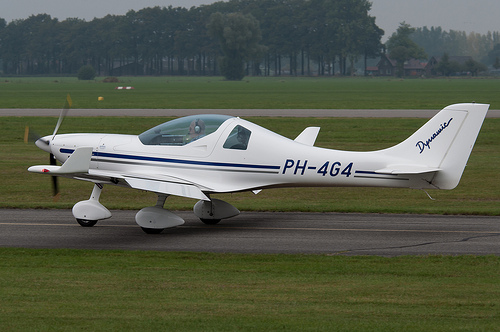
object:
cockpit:
[112, 113, 252, 159]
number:
[316, 161, 353, 178]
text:
[415, 117, 453, 154]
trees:
[0, 17, 23, 77]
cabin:
[365, 54, 425, 77]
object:
[97, 96, 103, 101]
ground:
[1, 90, 302, 114]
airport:
[209, 153, 498, 331]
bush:
[76, 64, 97, 81]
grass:
[0, 73, 69, 101]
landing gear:
[71, 182, 241, 235]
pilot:
[187, 118, 205, 139]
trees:
[282, 0, 362, 78]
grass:
[2, 253, 499, 332]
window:
[222, 124, 252, 151]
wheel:
[76, 218, 99, 227]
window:
[138, 114, 237, 146]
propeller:
[23, 93, 72, 197]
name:
[415, 117, 453, 154]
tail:
[374, 102, 491, 189]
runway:
[0, 206, 499, 254]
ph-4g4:
[282, 158, 354, 177]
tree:
[242, 0, 372, 78]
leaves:
[280, 15, 345, 40]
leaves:
[116, 26, 236, 47]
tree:
[119, 12, 209, 77]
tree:
[45, 21, 125, 62]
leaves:
[34, 18, 133, 79]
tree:
[201, 12, 290, 82]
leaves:
[217, 0, 321, 83]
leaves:
[382, 21, 428, 63]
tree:
[382, 20, 426, 77]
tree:
[23, 12, 113, 80]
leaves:
[32, 22, 106, 80]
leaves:
[74, 23, 154, 77]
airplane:
[27, 102, 490, 234]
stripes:
[58, 147, 280, 174]